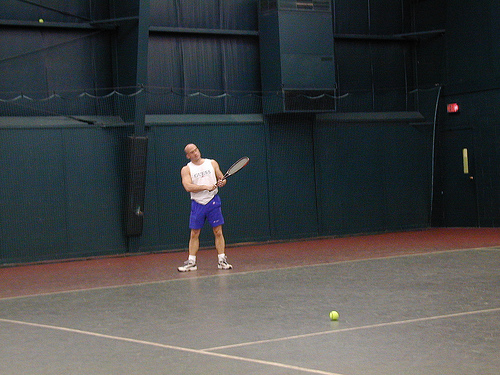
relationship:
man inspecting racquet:
[180, 143, 235, 274] [207, 149, 255, 195]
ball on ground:
[325, 306, 343, 325] [1, 225, 499, 373]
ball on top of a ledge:
[35, 15, 48, 25] [1, 17, 132, 35]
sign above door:
[445, 102, 460, 118] [441, 128, 482, 229]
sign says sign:
[445, 102, 460, 118] [445, 102, 460, 118]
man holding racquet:
[180, 143, 235, 274] [207, 149, 255, 195]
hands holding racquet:
[198, 179, 233, 198] [207, 149, 255, 195]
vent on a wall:
[257, 2, 338, 114] [1, 1, 500, 268]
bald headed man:
[181, 140, 203, 159] [180, 143, 235, 274]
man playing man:
[180, 143, 235, 274] [178, 143, 233, 273]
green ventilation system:
[255, 0, 339, 117] [257, 2, 338, 114]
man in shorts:
[180, 143, 235, 274] [183, 197, 224, 230]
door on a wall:
[441, 128, 482, 229] [416, 14, 496, 226]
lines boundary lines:
[1, 225, 499, 373] [2, 247, 500, 374]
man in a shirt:
[180, 143, 235, 274] [181, 158, 224, 205]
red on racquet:
[239, 159, 251, 172] [207, 149, 255, 195]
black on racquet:
[222, 170, 241, 180] [207, 149, 255, 195]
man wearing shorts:
[180, 143, 235, 274] [183, 197, 224, 230]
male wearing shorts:
[180, 143, 235, 274] [183, 197, 224, 230]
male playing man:
[180, 143, 235, 274] [178, 143, 233, 273]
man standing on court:
[180, 143, 235, 274] [1, 225, 499, 373]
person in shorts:
[180, 143, 235, 274] [183, 197, 224, 230]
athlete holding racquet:
[180, 143, 235, 274] [207, 149, 255, 195]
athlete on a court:
[180, 143, 235, 274] [1, 225, 499, 373]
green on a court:
[325, 306, 343, 325] [1, 225, 499, 373]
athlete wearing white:
[180, 143, 235, 274] [181, 158, 224, 205]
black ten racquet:
[222, 170, 241, 180] [207, 149, 255, 195]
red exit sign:
[239, 159, 251, 172] [445, 102, 460, 118]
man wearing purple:
[180, 143, 235, 274] [183, 197, 224, 230]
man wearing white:
[180, 143, 235, 274] [181, 158, 224, 205]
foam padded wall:
[1, 115, 436, 272] [1, 1, 500, 268]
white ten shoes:
[177, 259, 200, 275] [176, 254, 234, 274]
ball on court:
[325, 306, 343, 325] [1, 225, 499, 373]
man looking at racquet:
[180, 143, 235, 274] [207, 149, 255, 195]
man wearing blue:
[180, 143, 235, 274] [183, 197, 224, 230]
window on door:
[461, 148, 469, 178] [441, 128, 482, 229]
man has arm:
[180, 143, 235, 274] [178, 160, 214, 196]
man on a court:
[180, 143, 235, 274] [1, 225, 499, 373]